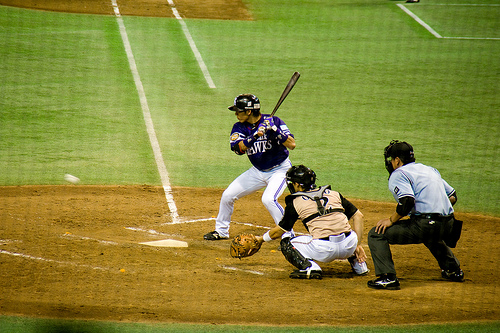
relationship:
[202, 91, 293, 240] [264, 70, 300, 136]
man with bat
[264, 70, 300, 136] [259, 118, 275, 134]
bat in hand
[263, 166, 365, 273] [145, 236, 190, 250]
catcher behind plate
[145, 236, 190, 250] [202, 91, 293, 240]
plate under batter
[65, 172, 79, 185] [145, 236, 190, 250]
ball approaching plate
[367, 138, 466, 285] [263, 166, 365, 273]
umpire behind catcher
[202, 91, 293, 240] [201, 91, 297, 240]
pants on legs of man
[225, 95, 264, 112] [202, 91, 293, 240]
helmet on top of man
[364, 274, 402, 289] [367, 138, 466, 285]
shoe on left of umpire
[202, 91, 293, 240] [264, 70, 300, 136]
man at bat